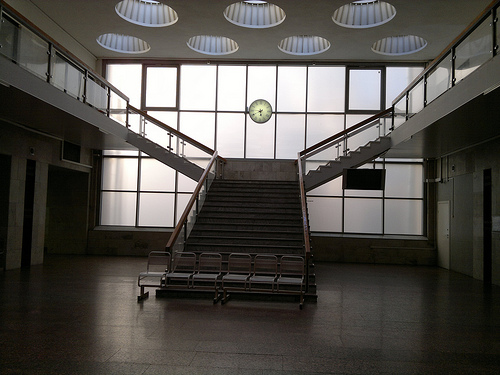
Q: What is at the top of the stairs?
A: Clock.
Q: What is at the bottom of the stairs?
A: Chairs.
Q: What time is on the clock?
A: Six pm.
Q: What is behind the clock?
A: Windows.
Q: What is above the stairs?
A: Lights.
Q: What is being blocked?
A: Stairs.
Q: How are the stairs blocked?
A: Chairs.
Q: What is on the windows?
A: Clock.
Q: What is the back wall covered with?
A: Windows.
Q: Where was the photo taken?
A: School.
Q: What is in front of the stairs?
A: Chairs.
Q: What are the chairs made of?
A: Metal.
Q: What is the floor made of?
A: Ceramic.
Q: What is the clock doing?
A: Lit.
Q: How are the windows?
A: Frosted.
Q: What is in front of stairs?
A: Benches.